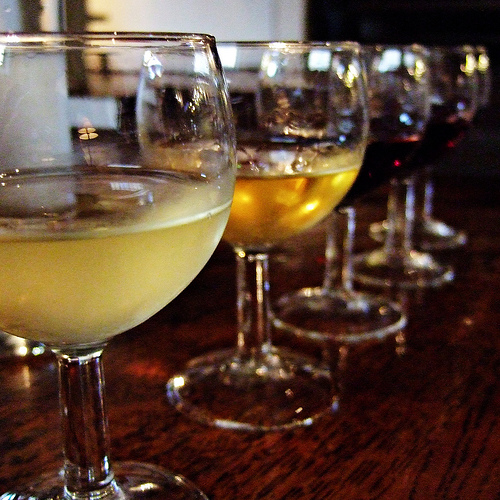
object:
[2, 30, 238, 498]
glass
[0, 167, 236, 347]
wine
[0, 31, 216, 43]
rim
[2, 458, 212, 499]
base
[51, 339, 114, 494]
stem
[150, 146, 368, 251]
wine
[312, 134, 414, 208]
wine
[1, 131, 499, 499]
table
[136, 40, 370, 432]
glass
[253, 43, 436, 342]
glass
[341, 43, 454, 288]
glass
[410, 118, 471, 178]
wine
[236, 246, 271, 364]
stem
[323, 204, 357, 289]
stem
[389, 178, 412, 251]
stem